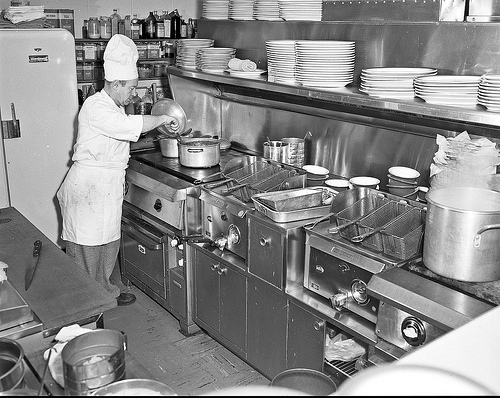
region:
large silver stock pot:
[418, 187, 497, 289]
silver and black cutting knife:
[10, 236, 74, 303]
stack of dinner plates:
[267, 35, 378, 99]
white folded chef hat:
[97, 36, 155, 100]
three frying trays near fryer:
[329, 191, 432, 269]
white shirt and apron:
[66, 99, 131, 255]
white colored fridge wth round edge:
[16, 8, 82, 163]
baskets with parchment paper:
[427, 128, 488, 200]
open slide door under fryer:
[306, 315, 371, 384]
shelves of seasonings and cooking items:
[77, 25, 184, 98]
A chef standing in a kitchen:
[57, 20, 157, 317]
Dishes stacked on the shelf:
[175, 20, 495, 120]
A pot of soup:
[152, 107, 233, 169]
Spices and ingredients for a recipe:
[70, 0, 191, 36]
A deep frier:
[270, 185, 431, 311]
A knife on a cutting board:
[0, 186, 120, 333]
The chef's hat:
[95, 30, 148, 80]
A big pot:
[420, 150, 498, 281]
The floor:
[103, 308, 268, 389]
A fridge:
[3, 32, 75, 237]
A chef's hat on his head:
[81, 28, 151, 84]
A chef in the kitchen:
[52, 23, 171, 306]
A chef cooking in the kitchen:
[133, 97, 233, 178]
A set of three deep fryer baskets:
[202, 149, 294, 206]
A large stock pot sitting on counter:
[408, 180, 498, 315]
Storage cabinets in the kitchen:
[181, 238, 326, 388]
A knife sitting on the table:
[8, 228, 47, 295]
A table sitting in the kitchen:
[2, 204, 119, 358]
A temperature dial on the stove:
[136, 192, 182, 233]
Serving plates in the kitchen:
[172, 24, 498, 114]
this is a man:
[78, 20, 134, 247]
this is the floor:
[132, 317, 174, 368]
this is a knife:
[23, 230, 45, 278]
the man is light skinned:
[116, 86, 127, 95]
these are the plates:
[356, 67, 399, 93]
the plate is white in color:
[373, 65, 406, 78]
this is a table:
[48, 267, 73, 310]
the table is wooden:
[43, 266, 93, 328]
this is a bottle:
[171, 12, 181, 32]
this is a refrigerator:
[19, 51, 59, 131]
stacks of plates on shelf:
[258, 33, 498, 126]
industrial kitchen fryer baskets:
[302, 180, 427, 319]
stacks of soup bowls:
[298, 142, 443, 244]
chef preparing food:
[42, 17, 255, 314]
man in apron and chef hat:
[47, 10, 217, 320]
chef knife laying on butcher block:
[2, 206, 128, 342]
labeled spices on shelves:
[40, 2, 212, 124]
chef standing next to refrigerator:
[0, 18, 185, 322]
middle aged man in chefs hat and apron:
[52, 15, 246, 332]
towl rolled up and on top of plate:
[227, 50, 273, 90]